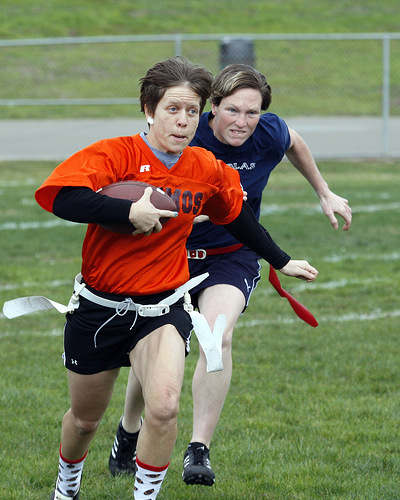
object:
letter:
[141, 161, 150, 179]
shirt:
[38, 134, 242, 294]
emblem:
[70, 356, 80, 365]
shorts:
[59, 278, 196, 376]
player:
[34, 54, 320, 500]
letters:
[131, 186, 203, 219]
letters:
[226, 157, 258, 173]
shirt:
[174, 109, 290, 256]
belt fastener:
[185, 249, 204, 261]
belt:
[187, 243, 245, 263]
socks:
[53, 449, 174, 500]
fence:
[0, 30, 400, 159]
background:
[0, 0, 399, 499]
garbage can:
[214, 38, 253, 74]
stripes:
[184, 441, 215, 487]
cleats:
[109, 417, 215, 488]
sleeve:
[52, 182, 133, 228]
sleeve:
[226, 197, 293, 275]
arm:
[34, 136, 129, 229]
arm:
[190, 144, 292, 272]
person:
[35, 56, 353, 500]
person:
[101, 58, 359, 487]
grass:
[0, 0, 399, 500]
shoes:
[110, 422, 218, 484]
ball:
[92, 182, 176, 233]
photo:
[0, 0, 399, 500]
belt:
[69, 268, 215, 318]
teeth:
[229, 127, 247, 134]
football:
[0, 0, 399, 500]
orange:
[37, 136, 243, 291]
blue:
[168, 107, 289, 312]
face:
[154, 83, 200, 152]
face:
[217, 86, 261, 149]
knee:
[141, 384, 183, 424]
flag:
[190, 308, 226, 372]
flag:
[264, 261, 321, 329]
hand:
[128, 186, 183, 239]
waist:
[75, 271, 189, 306]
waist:
[185, 236, 259, 262]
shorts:
[174, 243, 262, 312]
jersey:
[34, 136, 248, 297]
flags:
[0, 290, 85, 328]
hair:
[139, 56, 217, 127]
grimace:
[166, 128, 186, 142]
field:
[0, 0, 400, 121]